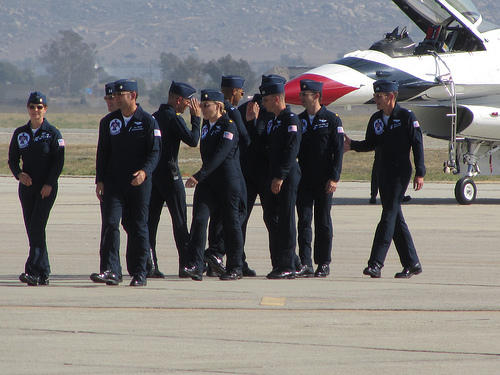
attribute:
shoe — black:
[19, 270, 38, 287]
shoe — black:
[41, 271, 48, 281]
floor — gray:
[135, 294, 255, 366]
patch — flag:
[218, 127, 238, 141]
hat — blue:
[20, 87, 52, 100]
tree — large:
[32, 25, 96, 112]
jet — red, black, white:
[283, 0, 496, 201]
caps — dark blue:
[103, 77, 138, 94]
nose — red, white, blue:
[276, 41, 443, 111]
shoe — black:
[311, 259, 334, 278]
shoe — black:
[391, 259, 424, 278]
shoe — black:
[360, 259, 383, 279]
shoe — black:
[177, 263, 206, 283]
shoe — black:
[86, 269, 121, 287]